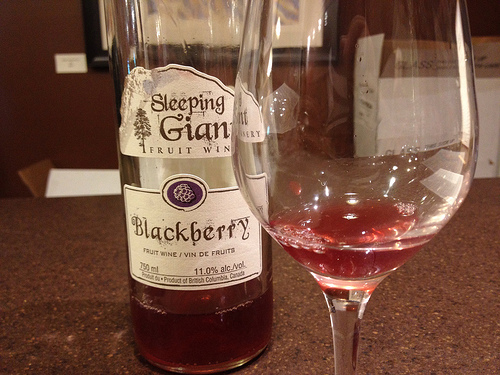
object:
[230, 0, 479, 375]
glass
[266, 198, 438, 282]
wine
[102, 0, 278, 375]
bottle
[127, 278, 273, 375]
wine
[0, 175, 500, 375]
counter top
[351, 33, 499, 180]
box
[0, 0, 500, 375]
scene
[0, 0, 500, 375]
inside